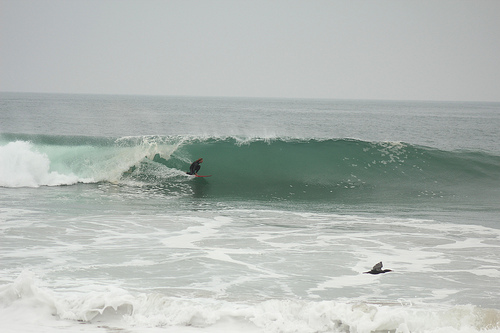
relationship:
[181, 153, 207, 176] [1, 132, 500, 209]
surfer riding wave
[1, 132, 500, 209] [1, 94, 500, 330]
wave crashing into ocean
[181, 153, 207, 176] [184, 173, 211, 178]
surfer crouching on board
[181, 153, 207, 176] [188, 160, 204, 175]
surfer wearing wetsuit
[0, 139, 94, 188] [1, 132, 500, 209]
foam of a wave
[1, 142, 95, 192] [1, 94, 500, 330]
foam lapping in ocean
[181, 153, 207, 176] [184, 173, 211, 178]
surfer using board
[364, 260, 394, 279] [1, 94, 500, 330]
bird flying over ocean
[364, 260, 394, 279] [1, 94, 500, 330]
bird flying above ocean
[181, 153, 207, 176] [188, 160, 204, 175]
surfer has wetsuit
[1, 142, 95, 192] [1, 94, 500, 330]
foam on ocean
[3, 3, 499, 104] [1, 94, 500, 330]
sky over ocean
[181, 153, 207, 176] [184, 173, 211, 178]
surfer riding on board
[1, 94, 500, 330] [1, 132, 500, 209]
ocean behind wave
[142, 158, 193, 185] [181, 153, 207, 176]
wake behind surfer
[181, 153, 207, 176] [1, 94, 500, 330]
surfer surfing in ocean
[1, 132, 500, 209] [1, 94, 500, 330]
wave in ocean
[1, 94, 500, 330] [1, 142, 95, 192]
ocean has foam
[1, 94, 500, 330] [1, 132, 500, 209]
ocean has wave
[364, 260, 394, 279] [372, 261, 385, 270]
bird has wing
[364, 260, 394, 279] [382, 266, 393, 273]
bird has head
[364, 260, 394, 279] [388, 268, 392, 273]
bird has beak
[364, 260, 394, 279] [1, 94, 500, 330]
bird over ocean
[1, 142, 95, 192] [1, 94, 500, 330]
foam in ocean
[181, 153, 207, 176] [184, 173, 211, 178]
surfer kneeling on board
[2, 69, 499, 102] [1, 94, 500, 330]
horizon over ocean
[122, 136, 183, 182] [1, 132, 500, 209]
curl inside wave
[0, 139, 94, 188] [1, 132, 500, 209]
foam of wave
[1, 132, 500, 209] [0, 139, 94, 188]
wave has foam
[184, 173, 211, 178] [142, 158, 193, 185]
board leaves behind wake